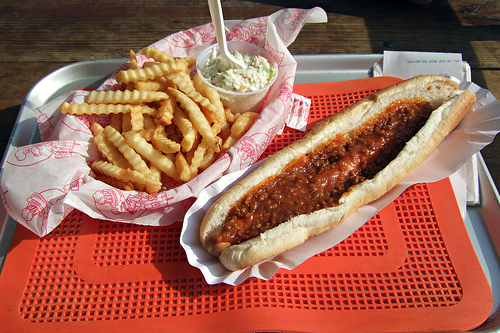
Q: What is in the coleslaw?
A: A fork.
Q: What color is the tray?
A: Orange.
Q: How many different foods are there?
A: Three.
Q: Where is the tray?
A: On a table.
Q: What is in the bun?
A: A hot dog with sauce.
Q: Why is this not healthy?
A: It's greasy food.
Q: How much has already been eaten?
A: None.